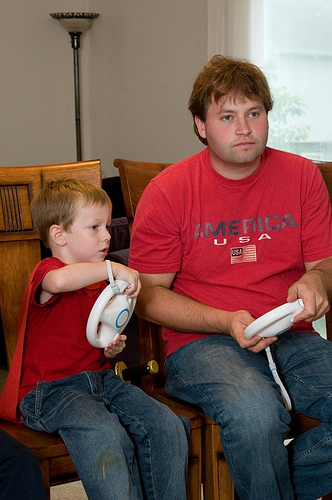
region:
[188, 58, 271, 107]
brown hair on head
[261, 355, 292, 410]
white cord hanging down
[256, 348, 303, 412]
white wire hanging down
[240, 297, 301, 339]
plastic steering wheel in handss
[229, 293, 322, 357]
hands holding plastic steering wheel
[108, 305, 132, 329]
blue circle on middle of wheel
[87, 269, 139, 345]
white plastic steering wheel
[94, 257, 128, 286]
white strap around wrist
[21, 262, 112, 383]
red shirt on kid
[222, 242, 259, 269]
american flag on shirt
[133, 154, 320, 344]
the shirt is red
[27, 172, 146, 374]
boy is holding a controller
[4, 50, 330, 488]
a man and kid playing Wii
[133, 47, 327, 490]
a man playing Wii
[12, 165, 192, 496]
a boy playing Wii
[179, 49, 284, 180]
the head of a man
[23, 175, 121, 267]
the head of a boy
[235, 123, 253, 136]
the nose of a man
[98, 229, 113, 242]
the nose of a boy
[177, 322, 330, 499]
the bluejeans of a man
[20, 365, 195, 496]
the bluejeans of a boy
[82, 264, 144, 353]
a white Wii controller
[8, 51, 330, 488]
a boy and a man playing a game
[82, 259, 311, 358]
controllers to a game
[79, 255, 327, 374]
steering wheel game controllers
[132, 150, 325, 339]
a man wearing a red shirt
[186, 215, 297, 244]
shirt says America USA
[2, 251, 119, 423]
a boy wearing a cape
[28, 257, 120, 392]
a boy wearing a red shirt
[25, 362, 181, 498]
a boy wearing blue jeans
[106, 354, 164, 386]
a handle to a sword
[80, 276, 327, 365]
father & son playing with steering wheels for mario kart racing games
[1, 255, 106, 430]
a little red cape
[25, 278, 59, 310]
a little pale armpit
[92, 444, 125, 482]
a medium size grass stain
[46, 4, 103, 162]
an standing lamp on a reasonably heavy silvertone metal base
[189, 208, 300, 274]
'AMERICA' :: 'U S A' :: 'USA' AGAIN in a flag, all of which figures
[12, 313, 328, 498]
2 more or less matching pairs of pants